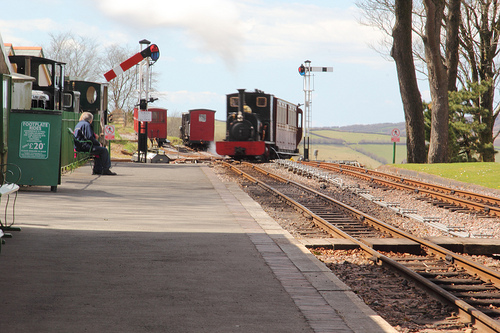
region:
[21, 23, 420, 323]
train on train tracks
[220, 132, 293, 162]
back red piece of train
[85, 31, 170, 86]
yellow and red train sign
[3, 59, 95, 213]
green trashcan by train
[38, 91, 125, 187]
bench at train station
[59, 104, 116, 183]
man sitting on bench at station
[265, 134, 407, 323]
train tracks by station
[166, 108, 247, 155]
red train by other train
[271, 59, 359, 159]
metal pole with train lights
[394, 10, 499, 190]
trees and grass on terrain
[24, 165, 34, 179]
the trash can is green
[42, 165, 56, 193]
the trash can is green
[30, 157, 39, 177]
the trash can is green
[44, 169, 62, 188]
the trash can is green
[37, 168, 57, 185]
the trash can is green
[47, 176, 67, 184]
the trash can is green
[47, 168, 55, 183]
the trash can is green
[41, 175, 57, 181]
the trash can is green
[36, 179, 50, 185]
the trash can is green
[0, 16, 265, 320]
Train station platform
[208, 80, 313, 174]
Black and red train engine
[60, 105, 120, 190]
Person sitting on a bench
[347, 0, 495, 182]
Old trees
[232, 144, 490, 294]
Railroad tracks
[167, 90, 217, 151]
Back of a train engine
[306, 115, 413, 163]
Green hills divided by boundaries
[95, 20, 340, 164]
Two train station signs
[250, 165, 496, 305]
Gravel between train tracks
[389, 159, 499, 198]
Short green grass growing beside train tracks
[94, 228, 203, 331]
the shadow is on the pavement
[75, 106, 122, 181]
the man is sitted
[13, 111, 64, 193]
the trashbin is green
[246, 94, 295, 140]
the train is black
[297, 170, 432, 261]
the rails are rusty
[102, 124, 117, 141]
the sign says do not crosss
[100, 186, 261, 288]
the pavement is concrete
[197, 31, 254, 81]
smoke is coming from the train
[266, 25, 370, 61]
there are clouds in the sky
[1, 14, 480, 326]
the day is sunny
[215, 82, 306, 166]
Locomotive changing direction on the tracks.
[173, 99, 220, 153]
Train car facing away from the station.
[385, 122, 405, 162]
Sign posted along the tracks to provide direction.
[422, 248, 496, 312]
Rusted steel train tracks.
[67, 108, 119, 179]
Person sitting on a bench awaiting a train.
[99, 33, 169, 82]
Traffic signal indication direction to the train.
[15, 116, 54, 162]
Sign stating the prices for tickets.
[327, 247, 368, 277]
Stones lining the tracks.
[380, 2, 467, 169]
Tall, strong tree trunks.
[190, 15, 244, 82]
Smoke rising from the engine.